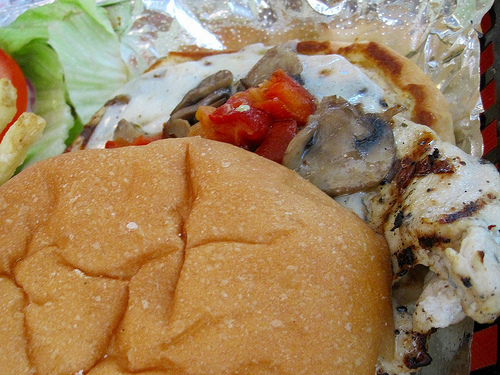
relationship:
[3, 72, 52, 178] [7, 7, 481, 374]
french fry on plate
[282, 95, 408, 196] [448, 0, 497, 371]
mushroom on a plate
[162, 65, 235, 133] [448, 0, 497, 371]
mushroom on a plate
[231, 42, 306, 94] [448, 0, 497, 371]
mushroom on a plate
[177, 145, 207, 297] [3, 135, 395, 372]
crease on a bun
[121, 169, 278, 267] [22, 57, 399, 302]
bun on sandwich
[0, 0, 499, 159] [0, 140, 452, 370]
aluminum foil under sandwich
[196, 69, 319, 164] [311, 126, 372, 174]
tomato on mushrooms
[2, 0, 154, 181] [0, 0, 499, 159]
lettuce on aluminum foil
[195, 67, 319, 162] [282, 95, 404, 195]
tomato on mushroom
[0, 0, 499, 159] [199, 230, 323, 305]
aluminum foil under bun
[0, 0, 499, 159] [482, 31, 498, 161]
aluminum foil on rack